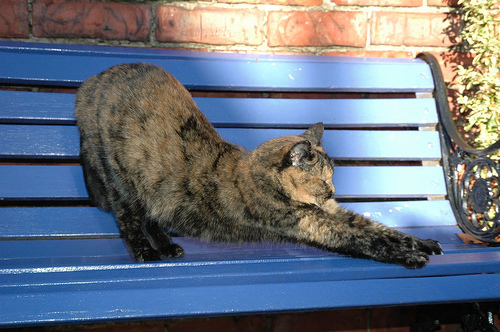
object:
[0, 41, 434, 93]
panel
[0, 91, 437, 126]
panel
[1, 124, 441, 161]
panel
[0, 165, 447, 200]
panel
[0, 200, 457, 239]
panel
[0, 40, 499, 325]
bench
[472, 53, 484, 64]
leaves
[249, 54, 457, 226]
sun